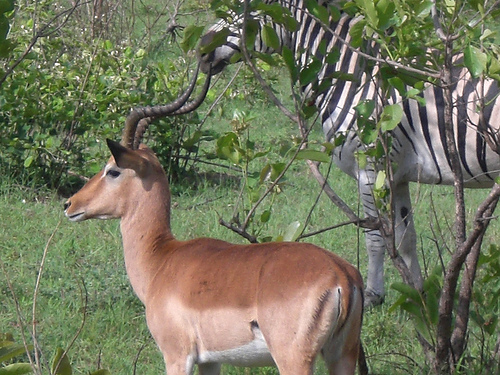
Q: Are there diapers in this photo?
A: No, there are no diapers.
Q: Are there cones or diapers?
A: No, there are no diapers or cones.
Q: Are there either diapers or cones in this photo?
A: No, there are no diapers or cones.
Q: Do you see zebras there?
A: Yes, there is a zebra.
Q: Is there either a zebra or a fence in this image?
A: Yes, there is a zebra.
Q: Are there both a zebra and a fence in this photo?
A: No, there is a zebra but no fences.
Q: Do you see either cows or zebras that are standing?
A: Yes, the zebra is standing.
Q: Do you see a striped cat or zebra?
A: Yes, there is a striped zebra.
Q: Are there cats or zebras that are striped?
A: Yes, the zebra is striped.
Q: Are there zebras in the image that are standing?
A: Yes, there is a zebra that is standing.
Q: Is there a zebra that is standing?
A: Yes, there is a zebra that is standing.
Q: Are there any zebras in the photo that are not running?
A: Yes, there is a zebra that is standing.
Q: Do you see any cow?
A: No, there are no cows.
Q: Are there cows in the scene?
A: No, there are no cows.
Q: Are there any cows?
A: No, there are no cows.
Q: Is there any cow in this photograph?
A: No, there are no cows.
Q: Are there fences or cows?
A: No, there are no cows or fences.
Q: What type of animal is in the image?
A: The animal is a zebra.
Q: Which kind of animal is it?
A: The animal is a zebra.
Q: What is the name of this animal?
A: This is a zebra.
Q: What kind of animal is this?
A: This is a zebra.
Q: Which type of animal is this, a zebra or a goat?
A: This is a zebra.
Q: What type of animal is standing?
A: The animal is a zebra.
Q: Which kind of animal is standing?
A: The animal is a zebra.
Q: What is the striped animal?
A: The animal is a zebra.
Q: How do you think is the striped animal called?
A: The animal is a zebra.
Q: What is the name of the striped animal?
A: The animal is a zebra.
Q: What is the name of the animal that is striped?
A: The animal is a zebra.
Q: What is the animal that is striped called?
A: The animal is a zebra.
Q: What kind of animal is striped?
A: The animal is a zebra.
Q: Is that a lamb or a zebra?
A: That is a zebra.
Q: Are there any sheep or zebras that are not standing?
A: No, there is a zebra but it is standing.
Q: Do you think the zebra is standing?
A: Yes, the zebra is standing.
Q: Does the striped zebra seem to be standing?
A: Yes, the zebra is standing.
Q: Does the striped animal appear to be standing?
A: Yes, the zebra is standing.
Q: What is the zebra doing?
A: The zebra is standing.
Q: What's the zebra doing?
A: The zebra is standing.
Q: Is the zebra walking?
A: No, the zebra is standing.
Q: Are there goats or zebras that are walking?
A: No, there is a zebra but it is standing.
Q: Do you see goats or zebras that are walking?
A: No, there is a zebra but it is standing.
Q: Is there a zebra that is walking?
A: No, there is a zebra but it is standing.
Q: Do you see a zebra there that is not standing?
A: No, there is a zebra but it is standing.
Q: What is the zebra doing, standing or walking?
A: The zebra is standing.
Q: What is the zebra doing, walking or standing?
A: The zebra is standing.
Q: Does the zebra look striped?
A: Yes, the zebra is striped.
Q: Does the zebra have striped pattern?
A: Yes, the zebra is striped.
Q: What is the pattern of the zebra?
A: The zebra is striped.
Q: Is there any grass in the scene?
A: Yes, there is grass.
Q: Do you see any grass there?
A: Yes, there is grass.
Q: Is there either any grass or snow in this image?
A: Yes, there is grass.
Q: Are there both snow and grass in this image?
A: No, there is grass but no snow.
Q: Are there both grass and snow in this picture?
A: No, there is grass but no snow.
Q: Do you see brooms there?
A: No, there are no brooms.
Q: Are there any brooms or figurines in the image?
A: No, there are no brooms or figurines.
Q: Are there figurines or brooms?
A: No, there are no brooms or figurines.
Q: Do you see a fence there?
A: No, there are no fences.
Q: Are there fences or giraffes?
A: No, there are no fences or giraffes.